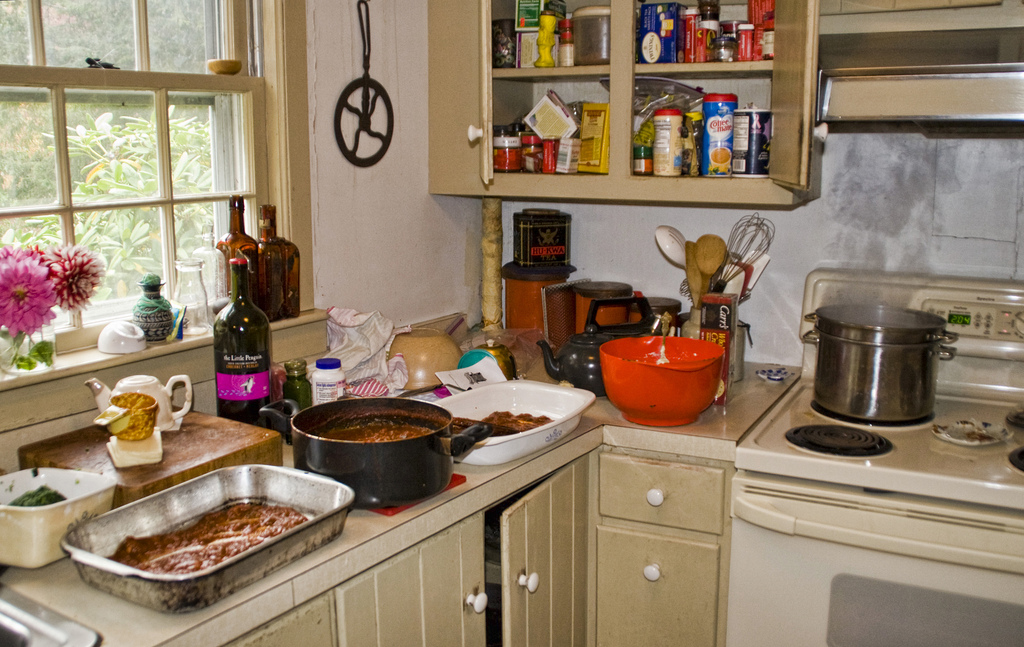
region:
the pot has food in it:
[273, 374, 488, 531]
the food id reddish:
[296, 371, 451, 495]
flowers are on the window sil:
[2, 209, 88, 368]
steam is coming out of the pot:
[788, 150, 962, 366]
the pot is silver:
[787, 260, 944, 435]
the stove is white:
[737, 197, 1009, 594]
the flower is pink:
[0, 248, 61, 353]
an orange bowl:
[599, 331, 727, 430]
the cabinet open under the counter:
[487, 459, 590, 640]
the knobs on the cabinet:
[460, 108, 831, 617]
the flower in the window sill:
[3, 231, 106, 378]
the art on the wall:
[329, 7, 400, 173]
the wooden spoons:
[675, 230, 734, 332]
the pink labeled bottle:
[211, 247, 275, 424]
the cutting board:
[12, 401, 284, 500]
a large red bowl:
[596, 341, 729, 425]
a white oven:
[705, 268, 1020, 643]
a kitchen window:
[5, 0, 252, 330]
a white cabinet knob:
[463, 591, 492, 611]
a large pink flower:
[0, 252, 67, 339]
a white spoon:
[653, 218, 691, 264]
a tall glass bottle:
[212, 259, 274, 425]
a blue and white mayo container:
[314, 352, 341, 398]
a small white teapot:
[81, 370, 195, 435]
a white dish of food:
[0, 464, 114, 569]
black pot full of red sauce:
[251, 395, 490, 512]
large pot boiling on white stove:
[731, 263, 1020, 644]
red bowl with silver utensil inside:
[595, 311, 728, 429]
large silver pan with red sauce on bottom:
[58, 456, 359, 613]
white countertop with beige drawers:
[5, 334, 806, 642]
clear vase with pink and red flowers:
[4, 241, 103, 381]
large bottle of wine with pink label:
[211, 254, 273, 425]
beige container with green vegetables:
[4, 464, 115, 567]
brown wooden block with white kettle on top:
[14, 373, 284, 509]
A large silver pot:
[789, 283, 968, 440]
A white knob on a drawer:
[626, 471, 677, 520]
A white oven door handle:
[721, 481, 1016, 586]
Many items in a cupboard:
[457, 1, 832, 214]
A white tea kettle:
[71, 359, 196, 435]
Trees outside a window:
[0, 0, 236, 334]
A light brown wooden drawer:
[579, 440, 734, 542]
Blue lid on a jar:
[305, 349, 351, 381]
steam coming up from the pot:
[816, 136, 944, 332]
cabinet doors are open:
[460, 4, 839, 212]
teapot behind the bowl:
[531, 296, 669, 393]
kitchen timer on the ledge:
[91, 320, 153, 355]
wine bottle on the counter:
[209, 258, 274, 425]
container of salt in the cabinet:
[726, 104, 773, 185]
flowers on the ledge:
[4, 253, 101, 365]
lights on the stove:
[993, 303, 1017, 349]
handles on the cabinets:
[639, 486, 672, 591]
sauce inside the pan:
[66, 460, 355, 608]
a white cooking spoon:
[649, 220, 687, 274]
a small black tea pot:
[528, 323, 614, 390]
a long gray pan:
[57, 461, 355, 642]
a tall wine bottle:
[198, 247, 272, 418]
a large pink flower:
[0, 256, 57, 337]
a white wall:
[294, 0, 473, 323]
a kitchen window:
[2, 0, 266, 333]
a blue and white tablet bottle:
[307, 353, 349, 410]